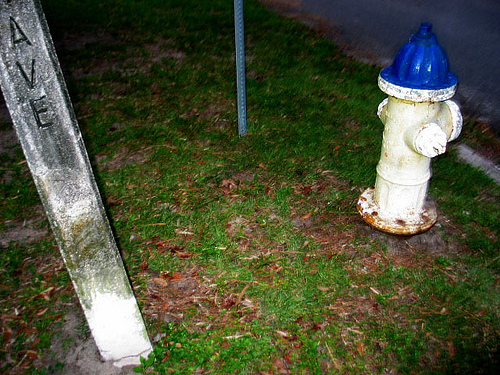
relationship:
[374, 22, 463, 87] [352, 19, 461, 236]
top of a fire hydrant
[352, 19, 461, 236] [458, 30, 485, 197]
fire hydrant on side of road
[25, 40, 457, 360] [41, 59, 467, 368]
ground covered in grass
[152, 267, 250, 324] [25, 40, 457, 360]
leaves laying on ground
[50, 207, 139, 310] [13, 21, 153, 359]
moss growing on post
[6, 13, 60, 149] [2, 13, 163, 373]
letters on post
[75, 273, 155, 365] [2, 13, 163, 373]
smudges on post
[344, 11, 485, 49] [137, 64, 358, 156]
concrete next grass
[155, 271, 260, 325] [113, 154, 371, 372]
patches on grass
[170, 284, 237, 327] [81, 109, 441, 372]
leaves on grass